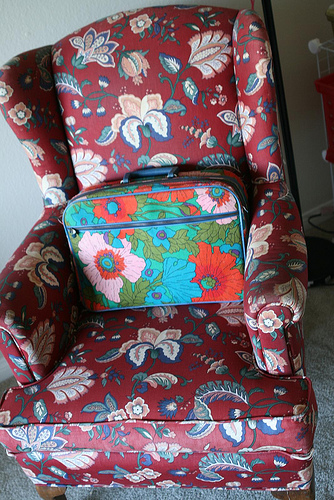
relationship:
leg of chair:
[272, 478, 317, 498] [1, 4, 320, 498]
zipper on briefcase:
[66, 214, 250, 236] [61, 164, 248, 310]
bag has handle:
[61, 166, 251, 312] [120, 163, 176, 183]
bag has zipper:
[61, 166, 251, 312] [66, 208, 239, 235]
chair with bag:
[1, 4, 320, 498] [61, 166, 251, 312]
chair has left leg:
[1, 4, 320, 498] [34, 480, 68, 497]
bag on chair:
[61, 166, 251, 312] [30, 29, 297, 395]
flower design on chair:
[70, 43, 182, 151] [1, 4, 320, 498]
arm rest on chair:
[244, 189, 310, 377] [1, 4, 320, 498]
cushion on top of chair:
[0, 297, 317, 460] [1, 4, 320, 498]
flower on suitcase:
[171, 241, 250, 353] [38, 126, 294, 310]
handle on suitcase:
[122, 165, 180, 184] [60, 164, 247, 313]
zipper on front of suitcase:
[65, 210, 239, 235] [60, 164, 247, 313]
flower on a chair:
[1, 4, 319, 497] [1, 4, 320, 498]